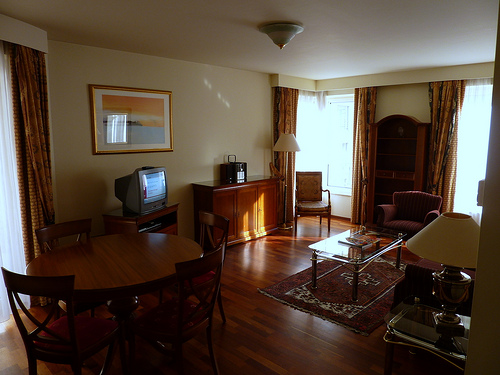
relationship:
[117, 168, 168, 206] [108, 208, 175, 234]
tv sitting on stand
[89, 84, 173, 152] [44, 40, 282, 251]
painting on wall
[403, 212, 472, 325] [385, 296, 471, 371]
lamp on small table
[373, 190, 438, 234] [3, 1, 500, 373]
arm chair in room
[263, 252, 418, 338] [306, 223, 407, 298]
rug under table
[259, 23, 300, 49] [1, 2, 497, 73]
light fixture on ceiling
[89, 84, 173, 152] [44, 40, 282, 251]
picture on wall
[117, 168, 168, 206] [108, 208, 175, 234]
television on stand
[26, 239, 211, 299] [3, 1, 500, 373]
table in room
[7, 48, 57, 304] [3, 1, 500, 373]
curtain in room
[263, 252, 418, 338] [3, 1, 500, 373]
carpet in room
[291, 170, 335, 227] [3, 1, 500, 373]
chair in room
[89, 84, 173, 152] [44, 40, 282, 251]
picture hanging on wall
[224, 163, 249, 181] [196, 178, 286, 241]
radio on stand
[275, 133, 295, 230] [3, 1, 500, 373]
lamp in room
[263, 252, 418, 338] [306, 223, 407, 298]
rug under coffee table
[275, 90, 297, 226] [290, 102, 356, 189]
curtain by window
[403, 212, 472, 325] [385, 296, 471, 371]
lamp on end table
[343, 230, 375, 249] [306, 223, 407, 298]
magazines on coffee table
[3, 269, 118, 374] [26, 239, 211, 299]
chair at table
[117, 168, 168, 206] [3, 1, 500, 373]
television in room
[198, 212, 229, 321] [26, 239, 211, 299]
chair around table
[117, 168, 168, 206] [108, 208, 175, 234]
television on tv stand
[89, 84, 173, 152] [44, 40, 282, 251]
painting hanging on wall